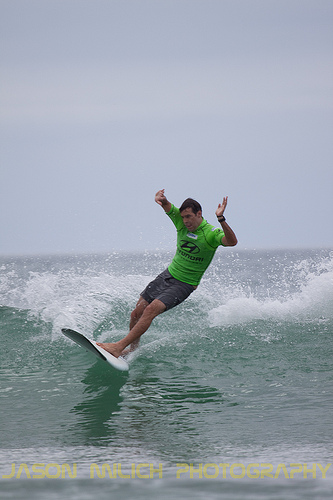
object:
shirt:
[163, 201, 225, 288]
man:
[95, 186, 238, 361]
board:
[60, 326, 130, 372]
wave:
[0, 246, 333, 373]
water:
[0, 243, 333, 497]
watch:
[216, 216, 227, 223]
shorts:
[139, 266, 199, 314]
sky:
[0, 0, 333, 256]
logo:
[179, 238, 201, 254]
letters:
[317, 460, 333, 482]